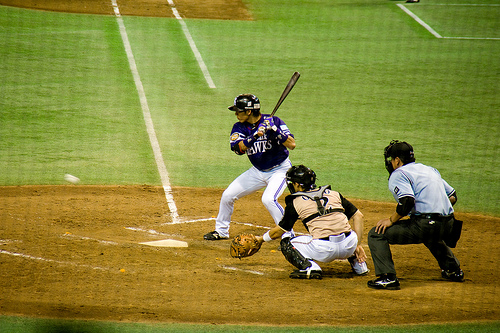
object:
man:
[201, 91, 297, 240]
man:
[363, 139, 465, 292]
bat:
[257, 71, 302, 137]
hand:
[372, 220, 393, 235]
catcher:
[252, 164, 371, 278]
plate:
[136, 238, 188, 249]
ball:
[64, 174, 79, 187]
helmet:
[225, 94, 259, 110]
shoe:
[365, 276, 402, 290]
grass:
[1, 0, 499, 219]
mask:
[284, 174, 295, 195]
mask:
[381, 147, 395, 180]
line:
[111, 0, 184, 223]